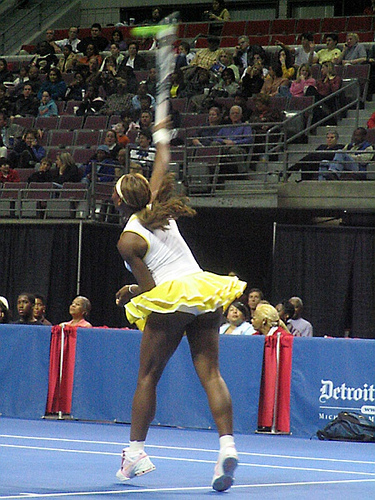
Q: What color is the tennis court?
A: Blue and white.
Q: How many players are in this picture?
A: One.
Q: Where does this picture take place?
A: On a tennis court.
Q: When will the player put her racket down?
A: After she has finished hitting the ball.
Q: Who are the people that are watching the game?
A: Spectators.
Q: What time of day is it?
A: Daytime.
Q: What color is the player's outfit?
A: Yellow and white.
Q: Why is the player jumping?
A: She is trying to hit the ball.